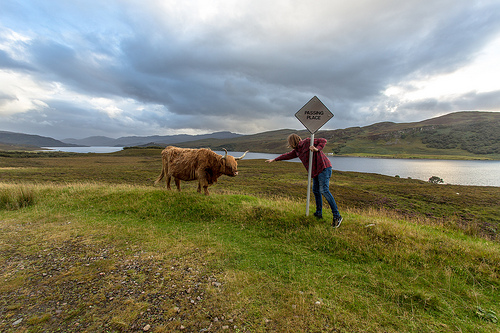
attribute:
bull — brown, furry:
[151, 136, 254, 194]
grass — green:
[3, 146, 495, 331]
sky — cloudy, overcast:
[2, 3, 497, 139]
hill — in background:
[63, 125, 245, 144]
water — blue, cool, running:
[35, 138, 128, 155]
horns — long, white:
[222, 144, 253, 161]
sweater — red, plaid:
[278, 138, 338, 176]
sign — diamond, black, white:
[294, 91, 334, 229]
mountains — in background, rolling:
[144, 110, 499, 155]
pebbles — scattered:
[1, 224, 295, 327]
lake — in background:
[192, 148, 500, 190]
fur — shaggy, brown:
[163, 144, 214, 182]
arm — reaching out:
[263, 152, 297, 165]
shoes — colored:
[308, 212, 346, 231]